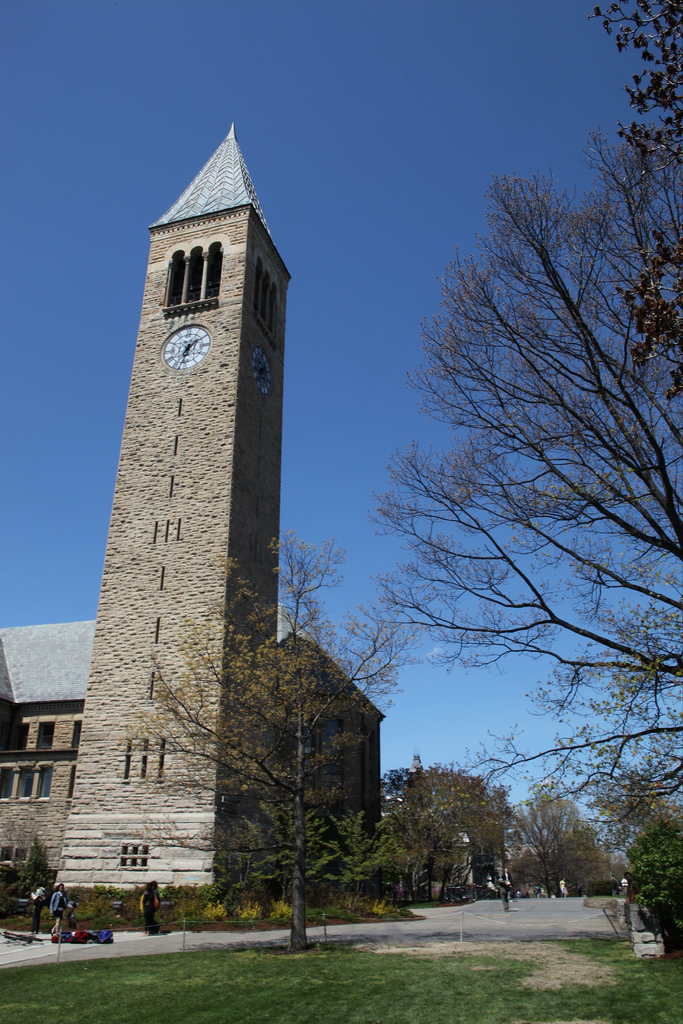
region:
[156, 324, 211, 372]
clock is round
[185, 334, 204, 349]
hour hand is black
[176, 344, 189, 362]
minute hand is black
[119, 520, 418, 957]
tree stands next to building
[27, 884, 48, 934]
human stands near tower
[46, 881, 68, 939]
human stands near tower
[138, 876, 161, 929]
human wears jacket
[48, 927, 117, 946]
bags are placed on ground in a group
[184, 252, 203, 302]
window is clean and clear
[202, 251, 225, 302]
window is clean and clear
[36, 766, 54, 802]
window is clean and clear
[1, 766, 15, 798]
window is clean and clear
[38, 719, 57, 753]
window is clean and clear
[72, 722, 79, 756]
window is clean and clear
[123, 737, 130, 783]
window is clean and clear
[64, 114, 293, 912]
tall stone clocktower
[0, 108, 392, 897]
old stone building with clocktower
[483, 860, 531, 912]
person in green pants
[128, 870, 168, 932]
person carying backpack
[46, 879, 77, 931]
person wearing blue jacket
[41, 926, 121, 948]
pile of red and blue backpacks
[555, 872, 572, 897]
person in yellow shirt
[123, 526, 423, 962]
tree with yellow leaves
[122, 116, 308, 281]
pointed green roof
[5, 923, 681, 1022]
green grassy lawn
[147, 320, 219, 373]
clock on a tower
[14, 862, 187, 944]
a group of people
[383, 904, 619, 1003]
a patch of dirt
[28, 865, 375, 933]
bushes around the building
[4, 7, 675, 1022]
a bright and clear day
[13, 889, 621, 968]
pavement next to building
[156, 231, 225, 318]
a set of windows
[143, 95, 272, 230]
steeple on the tower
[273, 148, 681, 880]
branches on the tree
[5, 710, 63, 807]
a set of windows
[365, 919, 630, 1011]
patch of dead grass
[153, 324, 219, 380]
Clock on a tower